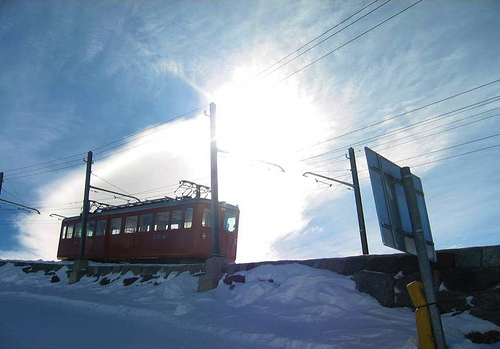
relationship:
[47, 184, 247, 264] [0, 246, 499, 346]
train on track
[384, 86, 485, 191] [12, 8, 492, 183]
electrical wires above tracks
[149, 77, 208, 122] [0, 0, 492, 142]
cloud in sky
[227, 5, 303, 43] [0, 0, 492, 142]
cloud in sky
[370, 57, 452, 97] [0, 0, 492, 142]
cloud in sky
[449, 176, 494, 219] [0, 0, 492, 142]
cloud in sky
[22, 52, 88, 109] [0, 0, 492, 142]
cloud in sky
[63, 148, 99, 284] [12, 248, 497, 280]
pole by tracks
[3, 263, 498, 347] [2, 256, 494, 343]
snow covers ground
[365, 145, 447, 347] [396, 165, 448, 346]
sign on sign pole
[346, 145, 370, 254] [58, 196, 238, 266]
pole has tram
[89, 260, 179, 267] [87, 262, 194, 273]
snow covers tracks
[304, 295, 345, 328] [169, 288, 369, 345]
part of snow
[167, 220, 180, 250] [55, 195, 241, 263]
part of train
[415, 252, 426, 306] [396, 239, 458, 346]
edge of post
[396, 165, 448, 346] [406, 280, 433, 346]
sign pole on yellow pole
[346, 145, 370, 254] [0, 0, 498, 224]
pole with electric lines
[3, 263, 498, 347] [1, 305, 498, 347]
snow on ground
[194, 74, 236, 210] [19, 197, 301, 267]
pole beside train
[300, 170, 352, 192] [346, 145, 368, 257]
light beside pole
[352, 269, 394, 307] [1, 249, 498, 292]
rock on side of tracks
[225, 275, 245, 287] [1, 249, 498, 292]
rock on side of tracks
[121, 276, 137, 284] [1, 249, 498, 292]
rock on side of tracks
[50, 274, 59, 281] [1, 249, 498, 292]
rock on side of tracks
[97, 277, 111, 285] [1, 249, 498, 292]
rock on side of tracks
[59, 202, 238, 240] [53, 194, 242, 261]
windows on train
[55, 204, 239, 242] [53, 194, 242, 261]
windows on train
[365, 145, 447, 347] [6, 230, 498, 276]
sign along side tracks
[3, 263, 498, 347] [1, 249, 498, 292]
snow beside tracks